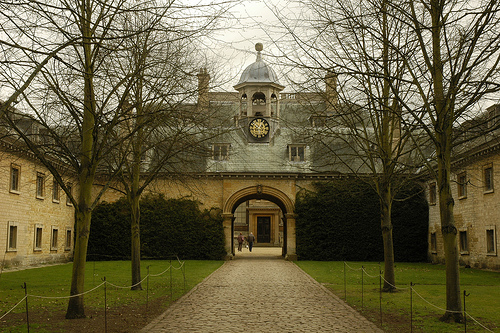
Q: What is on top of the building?
A: A tower.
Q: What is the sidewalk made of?
A: Cobblestone.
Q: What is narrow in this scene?
A: The road.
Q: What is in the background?
A: Green bushes.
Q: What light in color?
A: The building.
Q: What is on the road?
A: Two people.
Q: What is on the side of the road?
A: A fence guide.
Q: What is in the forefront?
A: Bare trees.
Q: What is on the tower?
A: A clock.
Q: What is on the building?
A: Many windows.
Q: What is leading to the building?
A: Sidewalk.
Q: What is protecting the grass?
A: Fence.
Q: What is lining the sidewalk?
A: Trees.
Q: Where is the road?
A: Center of courtyard.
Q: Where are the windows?
A: Buildings.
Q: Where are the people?
A: On the walkway.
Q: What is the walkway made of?
A: Cobblestone.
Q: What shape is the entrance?
A: Arch.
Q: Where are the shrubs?
A: Each side of the archway.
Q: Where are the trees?
A: In the grass.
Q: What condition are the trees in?
A: Bare.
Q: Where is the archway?
A: In the courtyard.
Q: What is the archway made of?
A: Stone.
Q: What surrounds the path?
A: Trees.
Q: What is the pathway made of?
A: Brick and stone.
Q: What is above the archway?
A: A building with a steeple.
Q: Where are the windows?
A: On the buildings.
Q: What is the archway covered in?
A: Green leaves and moss.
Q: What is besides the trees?
A: Small fenceposts.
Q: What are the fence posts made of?
A: Metal.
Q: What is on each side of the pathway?
A: Grass.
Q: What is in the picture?
A: Building.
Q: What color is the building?
A: Brown.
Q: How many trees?
A: Four.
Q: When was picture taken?
A: Daytime.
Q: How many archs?
A: One.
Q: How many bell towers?
A: One.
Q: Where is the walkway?
A: In the center.